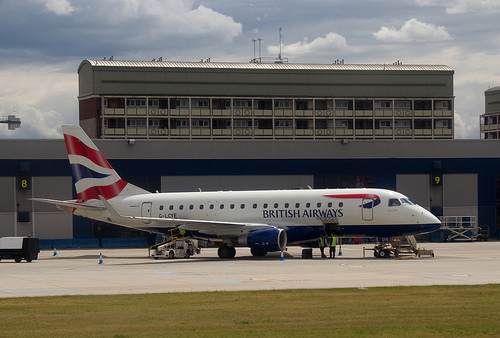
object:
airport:
[0, 48, 499, 337]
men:
[313, 232, 338, 263]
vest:
[316, 236, 337, 248]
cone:
[93, 243, 108, 271]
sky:
[0, 0, 499, 137]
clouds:
[0, 0, 499, 140]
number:
[13, 176, 33, 197]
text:
[253, 205, 352, 228]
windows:
[154, 201, 348, 209]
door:
[133, 196, 160, 231]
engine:
[229, 219, 291, 268]